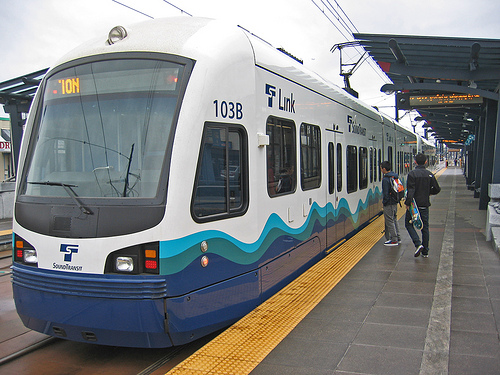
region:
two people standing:
[380, 148, 443, 258]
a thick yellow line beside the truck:
[163, 160, 447, 369]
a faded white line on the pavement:
[421, 161, 454, 373]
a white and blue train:
[11, 23, 434, 353]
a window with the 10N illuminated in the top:
[10, 50, 196, 245]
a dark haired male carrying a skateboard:
[401, 151, 441, 258]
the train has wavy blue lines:
[14, 23, 437, 355]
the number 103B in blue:
[211, 98, 245, 120]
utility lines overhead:
[320, 18, 378, 70]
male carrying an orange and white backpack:
[377, 157, 402, 244]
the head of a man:
[391, 145, 449, 185]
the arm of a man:
[399, 168, 435, 214]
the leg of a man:
[400, 197, 425, 262]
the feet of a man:
[407, 238, 447, 258]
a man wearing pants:
[401, 191, 464, 263]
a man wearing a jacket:
[362, 149, 422, 216]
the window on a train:
[16, 52, 225, 230]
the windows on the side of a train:
[179, 88, 402, 249]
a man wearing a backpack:
[385, 152, 425, 214]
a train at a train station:
[14, 54, 428, 347]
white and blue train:
[18, 2, 345, 350]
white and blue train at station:
[24, 10, 497, 373]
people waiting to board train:
[338, 101, 485, 266]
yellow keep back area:
[180, 210, 413, 352]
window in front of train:
[297, 114, 327, 199]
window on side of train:
[261, 112, 301, 199]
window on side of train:
[194, 114, 260, 222]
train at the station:
[20, 11, 464, 346]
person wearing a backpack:
[379, 168, 406, 220]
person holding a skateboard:
[404, 193, 431, 235]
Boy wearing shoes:
[382, 234, 402, 246]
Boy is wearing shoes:
[384, 236, 403, 248]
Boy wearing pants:
[379, 200, 404, 241]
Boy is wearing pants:
[380, 200, 402, 243]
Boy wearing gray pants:
[381, 200, 402, 241]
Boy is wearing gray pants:
[382, 200, 403, 242]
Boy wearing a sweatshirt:
[379, 169, 403, 207]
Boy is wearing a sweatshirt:
[379, 172, 400, 205]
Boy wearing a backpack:
[382, 175, 405, 206]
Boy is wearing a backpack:
[380, 171, 407, 206]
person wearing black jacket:
[395, 144, 452, 261]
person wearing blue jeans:
[391, 152, 443, 261]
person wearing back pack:
[365, 154, 412, 251]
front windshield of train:
[16, 54, 191, 235]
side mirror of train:
[180, 113, 264, 226]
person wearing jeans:
[367, 152, 405, 251]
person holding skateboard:
[397, 153, 446, 266]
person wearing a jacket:
[375, 156, 407, 253]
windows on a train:
[261, 105, 328, 198]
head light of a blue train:
[10, 232, 141, 283]